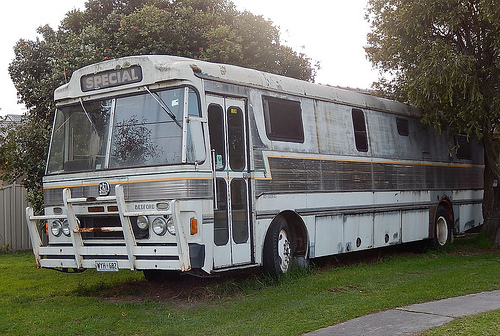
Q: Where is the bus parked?
A: On the grass, between the trees.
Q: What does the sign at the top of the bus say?
A: Special.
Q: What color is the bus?
A: Silver and white.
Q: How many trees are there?
A: Two.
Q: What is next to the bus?
A: A cement path.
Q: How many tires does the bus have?
A: Four.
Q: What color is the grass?
A: Green.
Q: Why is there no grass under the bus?
A: It's been parked there for a long time.